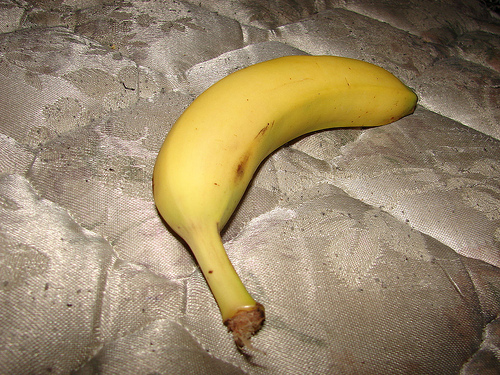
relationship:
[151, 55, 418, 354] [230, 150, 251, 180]
banana with dot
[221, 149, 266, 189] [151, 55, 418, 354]
dot on banana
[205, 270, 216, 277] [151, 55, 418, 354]
black dot on banana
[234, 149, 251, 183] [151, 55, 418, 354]
brown spots on banana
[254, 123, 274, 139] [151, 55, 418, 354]
brown spots on banana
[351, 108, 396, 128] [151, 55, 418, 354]
brown spots on banana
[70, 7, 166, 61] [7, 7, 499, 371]
flowers on cover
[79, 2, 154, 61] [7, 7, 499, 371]
stems on cover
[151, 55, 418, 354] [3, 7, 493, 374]
banana on quilt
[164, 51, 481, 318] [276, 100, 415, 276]
creases on bed cover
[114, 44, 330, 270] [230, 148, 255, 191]
banana with black dot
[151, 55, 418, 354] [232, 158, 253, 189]
banana with dot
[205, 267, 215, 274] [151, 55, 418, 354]
dot on banana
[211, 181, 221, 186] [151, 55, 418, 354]
dot on banana